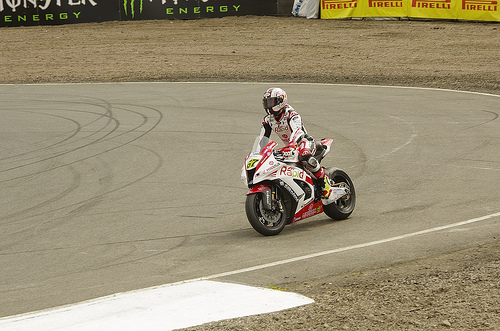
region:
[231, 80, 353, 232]
person riding motorcycle during race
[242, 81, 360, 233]
person riding motorcycle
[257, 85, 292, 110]
person wearing protective helmet during race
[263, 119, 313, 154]
person wearing protective clothing during race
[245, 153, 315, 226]
red and white motorcycle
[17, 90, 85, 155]
black motorcycle tracks on gray pavment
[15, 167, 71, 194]
black motorcycle tracks on gray pavment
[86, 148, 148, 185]
black motorcycle tracks on gray pavment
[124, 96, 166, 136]
black motorcycle tracks on gray pavment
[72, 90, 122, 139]
black motorcycle tracks on gray pavment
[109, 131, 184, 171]
race track for motorcycle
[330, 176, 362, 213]
back wheel on motorcycle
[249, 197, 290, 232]
front wheel on motorcycle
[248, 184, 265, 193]
front fender on motorcycle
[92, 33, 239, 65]
dirt near race track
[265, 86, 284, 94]
front part of helmet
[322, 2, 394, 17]
yellow banner on wall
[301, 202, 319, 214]
lower part of motorcycle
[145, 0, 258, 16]
words on advertising wall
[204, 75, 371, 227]
person on the motorcycle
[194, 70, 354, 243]
Person in white uniform riding motorcycle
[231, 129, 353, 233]
Red and white motorcycle being ridden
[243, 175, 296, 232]
Black tire of red and white motorcycle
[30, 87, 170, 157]
Tire marks on a gray asphalt course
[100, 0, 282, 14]
Black and green sign with the word Energy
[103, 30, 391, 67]
Light brown patch of dirt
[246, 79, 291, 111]
Black and white motorcycle helmet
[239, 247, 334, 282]
White line in gray asphalt course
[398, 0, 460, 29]
Yellow sign with red lettering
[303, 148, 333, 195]
Leg of person riding motorcycle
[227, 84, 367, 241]
person riding on motorcycle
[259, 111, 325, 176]
uniform of professional rider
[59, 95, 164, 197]
tire marks in track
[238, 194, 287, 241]
tire on front of bike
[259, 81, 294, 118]
helmet on rider's head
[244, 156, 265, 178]
number on front of bike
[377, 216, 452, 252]
white line on track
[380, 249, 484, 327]
gravel on side of track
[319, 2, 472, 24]
red and yellow banner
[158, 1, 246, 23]
green letters on black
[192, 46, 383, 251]
man riding a motorcycle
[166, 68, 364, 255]
man wearing a safety helmet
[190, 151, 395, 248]
motor cycle with black tires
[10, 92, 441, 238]
large dirt track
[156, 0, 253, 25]
advertisement with the letter e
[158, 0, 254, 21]
advertisement with the letter n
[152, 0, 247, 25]
advertisement with the letter r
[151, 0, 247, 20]
advertisement with the letter g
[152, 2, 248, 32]
advertisement with the letter y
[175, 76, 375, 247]
motor cycle with the letter r